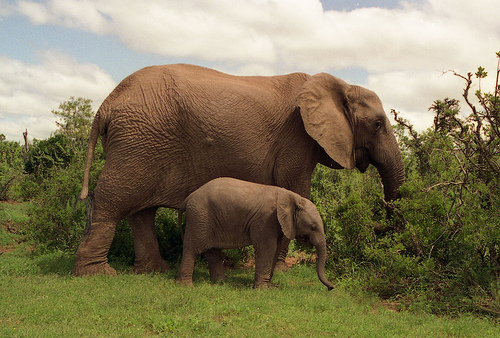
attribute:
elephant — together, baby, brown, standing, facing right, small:
[178, 174, 333, 295]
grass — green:
[2, 196, 499, 338]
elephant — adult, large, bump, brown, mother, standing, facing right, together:
[72, 63, 404, 275]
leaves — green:
[424, 225, 439, 244]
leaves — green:
[379, 236, 395, 250]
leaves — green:
[361, 245, 381, 261]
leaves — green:
[384, 250, 401, 268]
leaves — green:
[402, 255, 421, 273]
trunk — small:
[317, 246, 333, 293]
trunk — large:
[374, 138, 405, 217]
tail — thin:
[80, 101, 107, 200]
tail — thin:
[176, 198, 188, 245]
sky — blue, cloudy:
[0, 0, 497, 145]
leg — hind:
[204, 247, 238, 282]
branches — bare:
[459, 67, 483, 158]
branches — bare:
[476, 86, 500, 146]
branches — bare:
[422, 173, 468, 193]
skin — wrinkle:
[85, 76, 340, 277]